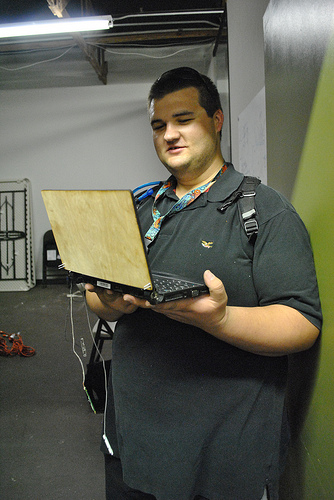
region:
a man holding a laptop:
[35, 54, 322, 472]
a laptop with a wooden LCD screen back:
[31, 187, 164, 291]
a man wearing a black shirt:
[112, 70, 322, 331]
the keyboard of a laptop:
[142, 267, 212, 304]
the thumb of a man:
[200, 267, 232, 301]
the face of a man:
[150, 110, 201, 157]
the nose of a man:
[161, 127, 185, 142]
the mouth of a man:
[162, 141, 188, 155]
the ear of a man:
[211, 107, 224, 136]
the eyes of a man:
[146, 112, 192, 130]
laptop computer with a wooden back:
[39, 180, 202, 305]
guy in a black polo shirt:
[71, 62, 331, 498]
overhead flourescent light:
[0, 7, 125, 46]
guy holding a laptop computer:
[41, 61, 321, 457]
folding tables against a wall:
[0, 171, 35, 319]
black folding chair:
[39, 224, 62, 295]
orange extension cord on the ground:
[2, 320, 45, 364]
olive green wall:
[258, 4, 333, 494]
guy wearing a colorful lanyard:
[70, 63, 300, 494]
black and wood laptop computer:
[35, 182, 222, 318]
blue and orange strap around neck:
[136, 160, 232, 262]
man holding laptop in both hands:
[39, 183, 242, 328]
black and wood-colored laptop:
[35, 183, 211, 304]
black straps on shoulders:
[126, 172, 282, 242]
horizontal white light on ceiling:
[2, 11, 115, 42]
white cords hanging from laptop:
[58, 268, 118, 456]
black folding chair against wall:
[39, 227, 73, 285]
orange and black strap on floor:
[0, 323, 42, 363]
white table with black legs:
[0, 175, 40, 292]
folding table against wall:
[1, 174, 39, 294]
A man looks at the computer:
[37, 68, 316, 310]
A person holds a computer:
[41, 189, 236, 335]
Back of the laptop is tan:
[41, 188, 150, 292]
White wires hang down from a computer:
[68, 282, 122, 464]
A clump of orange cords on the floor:
[2, 328, 36, 360]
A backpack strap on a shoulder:
[222, 173, 269, 254]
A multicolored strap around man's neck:
[146, 161, 232, 260]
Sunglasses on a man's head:
[150, 67, 231, 184]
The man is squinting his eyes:
[150, 114, 204, 134]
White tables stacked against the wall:
[0, 174, 41, 292]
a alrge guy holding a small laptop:
[39, 65, 322, 498]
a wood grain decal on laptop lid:
[38, 188, 152, 290]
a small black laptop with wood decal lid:
[40, 188, 216, 302]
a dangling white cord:
[67, 268, 114, 453]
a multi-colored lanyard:
[141, 167, 229, 257]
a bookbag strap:
[231, 168, 259, 236]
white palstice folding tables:
[1, 176, 36, 290]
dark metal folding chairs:
[42, 229, 73, 285]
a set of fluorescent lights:
[0, 13, 114, 38]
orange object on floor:
[1, 324, 36, 358]